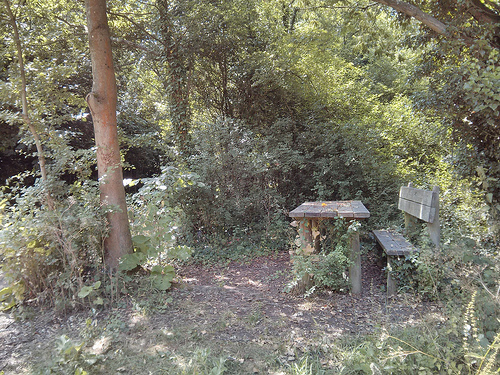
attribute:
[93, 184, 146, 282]
trunk — brown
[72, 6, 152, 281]
tree — here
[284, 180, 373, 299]
table — wooden, here, wood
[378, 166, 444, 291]
bench — wooden, here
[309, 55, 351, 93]
leaves — green, here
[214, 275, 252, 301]
dirt — here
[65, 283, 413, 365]
ground — here, dirt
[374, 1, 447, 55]
branch — leaning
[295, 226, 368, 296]
legs — wood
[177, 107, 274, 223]
shrubs — here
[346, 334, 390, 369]
grass — here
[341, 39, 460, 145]
vegetation — green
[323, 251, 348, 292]
plant — here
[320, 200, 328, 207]
leaf — brown